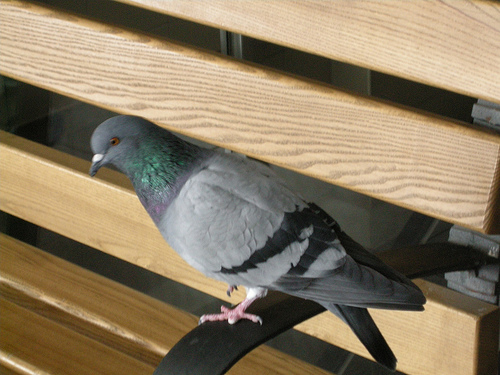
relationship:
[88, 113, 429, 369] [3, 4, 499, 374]
dove standing on bench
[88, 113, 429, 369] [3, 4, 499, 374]
dove on bench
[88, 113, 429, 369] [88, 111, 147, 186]
dove facing left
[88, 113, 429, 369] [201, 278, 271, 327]
dove has left leg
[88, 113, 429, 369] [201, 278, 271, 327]
dove standing on left leg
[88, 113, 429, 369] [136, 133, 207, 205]
dove has a neck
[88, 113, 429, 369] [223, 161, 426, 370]
dove has wings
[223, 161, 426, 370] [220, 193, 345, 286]
wings have some black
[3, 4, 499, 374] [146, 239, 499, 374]
bench has armrest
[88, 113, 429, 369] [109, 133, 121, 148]
dove has brown eye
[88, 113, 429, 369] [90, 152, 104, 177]
dove has a peak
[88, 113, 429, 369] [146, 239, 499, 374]
dove standing on armrest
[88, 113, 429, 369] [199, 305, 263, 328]
dove has pink foot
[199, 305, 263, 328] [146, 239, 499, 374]
pink foot on armrest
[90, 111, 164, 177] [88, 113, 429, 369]
head bent forward of dove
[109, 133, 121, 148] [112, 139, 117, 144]
brown eye has black pupil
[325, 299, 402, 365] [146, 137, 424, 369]
tail has gray feathers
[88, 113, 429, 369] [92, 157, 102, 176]
dove has beak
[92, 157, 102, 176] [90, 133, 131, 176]
beak on doves face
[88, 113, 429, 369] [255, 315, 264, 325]
dove has a toenail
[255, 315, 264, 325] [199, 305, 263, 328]
toenail on doves pink foot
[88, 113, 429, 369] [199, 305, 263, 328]
dove has a foot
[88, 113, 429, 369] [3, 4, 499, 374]
dove sitting n bench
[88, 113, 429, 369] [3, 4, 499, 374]
dove sitting on bench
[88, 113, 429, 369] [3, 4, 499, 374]
dove standing on a bench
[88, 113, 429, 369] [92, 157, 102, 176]
dove has a beak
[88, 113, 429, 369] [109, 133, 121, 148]
dove has orange eye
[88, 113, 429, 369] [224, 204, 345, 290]
dove has stripes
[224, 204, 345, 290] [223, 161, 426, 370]
stripes on wings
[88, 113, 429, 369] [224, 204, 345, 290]
dove has black stripes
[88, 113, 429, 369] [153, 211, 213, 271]
dove has a grey breast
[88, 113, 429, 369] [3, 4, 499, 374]
dove on a bench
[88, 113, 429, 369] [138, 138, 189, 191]
dove feathers are green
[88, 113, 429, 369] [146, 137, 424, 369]
dove has grey and black feathers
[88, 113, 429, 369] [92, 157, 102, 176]
dove has a spot on beak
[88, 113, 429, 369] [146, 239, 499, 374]
dove grip armrest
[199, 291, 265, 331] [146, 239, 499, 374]
feet gripping armrest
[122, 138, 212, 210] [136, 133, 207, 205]
tint on neck